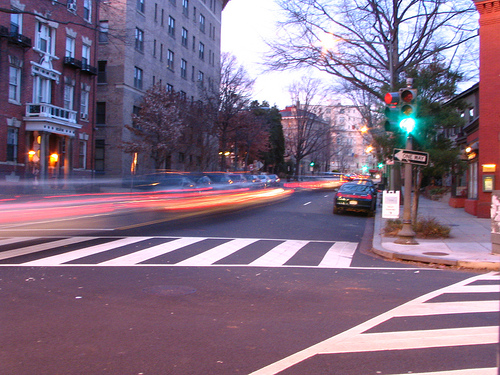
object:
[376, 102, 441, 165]
singal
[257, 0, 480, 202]
tree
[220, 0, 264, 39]
sky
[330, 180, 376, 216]
black care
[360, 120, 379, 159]
lights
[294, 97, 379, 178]
building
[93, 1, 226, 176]
building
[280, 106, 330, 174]
building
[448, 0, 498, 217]
building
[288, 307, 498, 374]
roadside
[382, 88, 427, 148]
traffic signal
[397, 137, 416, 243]
pole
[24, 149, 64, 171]
lights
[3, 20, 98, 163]
building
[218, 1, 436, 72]
clear sky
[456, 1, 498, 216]
red building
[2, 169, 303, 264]
cars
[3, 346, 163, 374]
street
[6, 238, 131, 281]
stripes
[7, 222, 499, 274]
crosswalk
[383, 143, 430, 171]
sign board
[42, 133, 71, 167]
entry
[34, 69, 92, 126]
terrace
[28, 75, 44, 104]
columns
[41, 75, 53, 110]
columns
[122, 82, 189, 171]
tree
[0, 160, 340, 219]
flashes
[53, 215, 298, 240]
street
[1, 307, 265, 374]
road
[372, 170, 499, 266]
curb